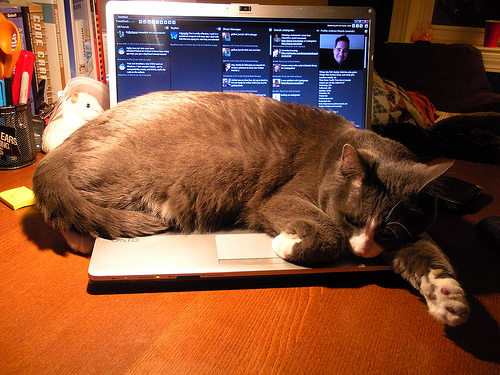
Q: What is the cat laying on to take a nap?
A: Laptop.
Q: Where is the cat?
A: On computer.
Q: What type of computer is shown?
A: Laptop.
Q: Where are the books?
A: Behind computer.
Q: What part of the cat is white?
A: Nose and paws.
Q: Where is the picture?
A: On computer screen.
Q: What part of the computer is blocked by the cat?
A: Keyboard.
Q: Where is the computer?
A: On desk.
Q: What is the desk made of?
A: Wood.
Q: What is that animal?
A: A cat.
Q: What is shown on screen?
A: A chat profile.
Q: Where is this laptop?
A: At someone's room.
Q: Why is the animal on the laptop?
A: To rest on it.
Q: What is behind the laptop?
A: A bunch of books.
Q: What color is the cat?
A: Grey.